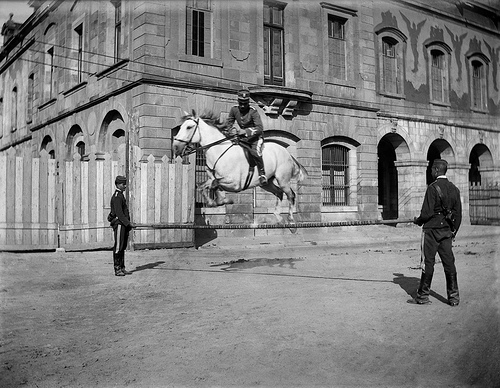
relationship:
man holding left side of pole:
[108, 175, 131, 277] [131, 217, 424, 230]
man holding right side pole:
[408, 158, 462, 305] [131, 217, 424, 230]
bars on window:
[196, 149, 224, 206] [194, 147, 228, 204]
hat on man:
[238, 91, 251, 103] [221, 92, 265, 185]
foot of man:
[121, 269, 132, 276] [108, 175, 131, 277]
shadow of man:
[126, 259, 164, 274] [108, 175, 131, 277]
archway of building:
[376, 133, 413, 228] [0, 0, 499, 250]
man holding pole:
[108, 175, 131, 277] [131, 217, 424, 230]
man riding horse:
[221, 92, 265, 185] [172, 109, 308, 233]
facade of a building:
[145, 1, 499, 249] [0, 0, 499, 250]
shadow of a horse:
[212, 256, 301, 276] [172, 109, 308, 233]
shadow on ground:
[152, 266, 394, 285] [0, 234, 499, 387]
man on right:
[108, 175, 131, 277] [0, 3, 256, 387]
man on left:
[408, 158, 462, 305] [228, 4, 499, 387]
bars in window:
[196, 149, 224, 206] [194, 147, 228, 204]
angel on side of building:
[400, 11, 428, 74] [0, 0, 499, 250]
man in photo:
[108, 175, 131, 277] [0, 1, 499, 387]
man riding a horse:
[221, 92, 265, 185] [172, 109, 308, 233]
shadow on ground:
[126, 259, 164, 274] [0, 234, 499, 387]